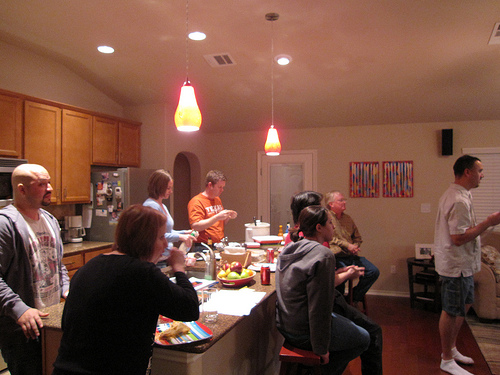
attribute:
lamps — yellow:
[175, 59, 293, 156]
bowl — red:
[214, 272, 255, 292]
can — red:
[258, 265, 275, 295]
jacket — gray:
[273, 234, 338, 356]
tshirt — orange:
[186, 193, 223, 241]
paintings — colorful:
[340, 153, 422, 209]